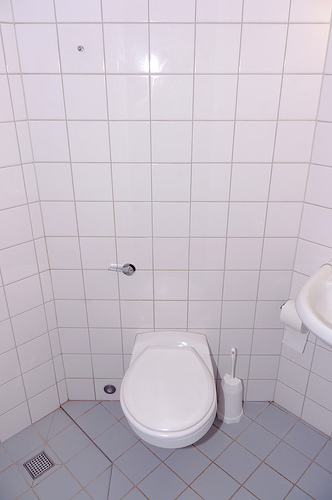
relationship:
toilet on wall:
[120, 331, 217, 450] [7, 0, 326, 411]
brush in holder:
[230, 350, 240, 378] [220, 378, 245, 426]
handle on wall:
[109, 263, 137, 277] [7, 0, 326, 411]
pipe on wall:
[101, 385, 118, 396] [7, 0, 326, 411]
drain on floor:
[24, 450, 56, 478] [3, 400, 330, 498]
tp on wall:
[278, 300, 310, 359] [7, 0, 326, 411]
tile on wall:
[150, 25, 193, 77] [7, 0, 326, 411]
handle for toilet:
[109, 263, 137, 277] [120, 331, 217, 450]